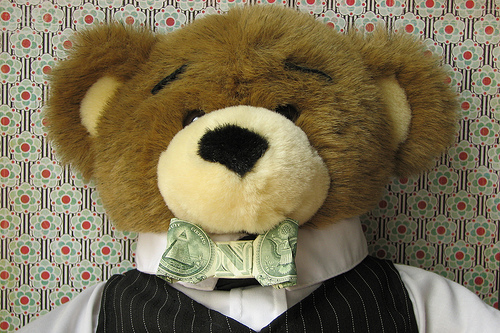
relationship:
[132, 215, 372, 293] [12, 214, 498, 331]
collar of shirt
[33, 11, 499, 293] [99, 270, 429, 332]
bear has on a vest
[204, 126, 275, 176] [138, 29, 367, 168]
nose on teddy bear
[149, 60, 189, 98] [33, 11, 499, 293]
eye brow on bear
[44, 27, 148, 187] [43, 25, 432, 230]
ear of teddy bear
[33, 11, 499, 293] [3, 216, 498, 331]
bear wearing a white shirt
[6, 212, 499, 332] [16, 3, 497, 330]
undershirt on teddybear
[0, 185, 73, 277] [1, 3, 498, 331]
floral pattern on backdrop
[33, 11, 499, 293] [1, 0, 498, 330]
bear against wall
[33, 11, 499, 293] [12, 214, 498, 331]
bear wearing shirt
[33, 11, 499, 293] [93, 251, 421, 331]
bear wearing vest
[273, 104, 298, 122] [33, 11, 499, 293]
eye on bear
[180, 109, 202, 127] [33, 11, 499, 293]
eye on bear